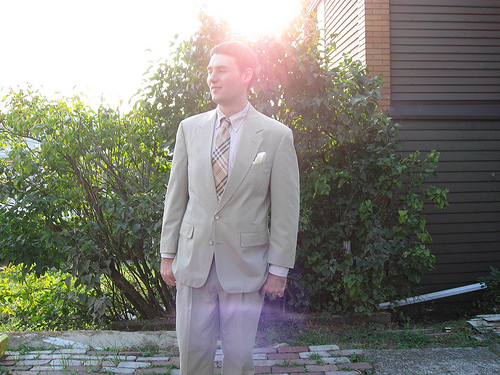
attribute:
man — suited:
[157, 42, 307, 371]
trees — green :
[14, 17, 447, 326]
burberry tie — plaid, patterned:
[208, 117, 235, 200]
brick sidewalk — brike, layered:
[4, 341, 365, 373]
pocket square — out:
[252, 152, 271, 166]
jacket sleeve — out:
[265, 265, 290, 279]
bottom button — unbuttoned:
[207, 238, 217, 249]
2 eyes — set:
[206, 65, 232, 76]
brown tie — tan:
[212, 116, 233, 195]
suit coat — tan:
[166, 106, 306, 265]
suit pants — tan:
[169, 268, 268, 374]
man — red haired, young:
[160, 36, 326, 366]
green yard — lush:
[1, 207, 154, 329]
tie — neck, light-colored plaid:
[212, 113, 236, 195]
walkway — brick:
[3, 326, 366, 374]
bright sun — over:
[206, 2, 313, 44]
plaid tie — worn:
[211, 116, 234, 198]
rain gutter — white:
[268, 0, 324, 38]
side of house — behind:
[282, 2, 389, 119]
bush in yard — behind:
[9, 11, 449, 317]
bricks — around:
[2, 346, 373, 374]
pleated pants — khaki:
[171, 278, 257, 375]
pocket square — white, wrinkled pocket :
[254, 153, 271, 165]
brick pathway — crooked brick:
[3, 344, 364, 375]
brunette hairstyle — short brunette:
[206, 39, 259, 79]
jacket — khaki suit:
[159, 108, 305, 273]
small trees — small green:
[5, 7, 458, 320]